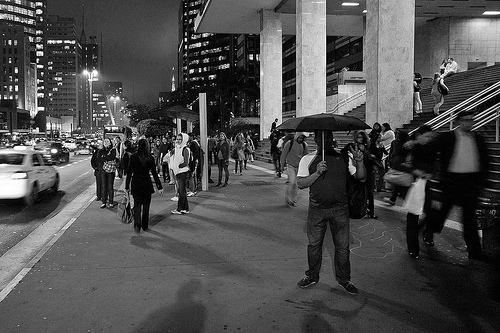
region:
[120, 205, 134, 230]
A gray bag in the photo.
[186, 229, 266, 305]
Road with tarmac in the photo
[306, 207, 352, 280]
Jeans in the photo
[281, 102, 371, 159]
Umbrella in the photo.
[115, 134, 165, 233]
A woman in the photo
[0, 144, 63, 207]
Car in the photo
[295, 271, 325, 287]
Black shoe in the photo.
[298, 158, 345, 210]
White and black t-shirt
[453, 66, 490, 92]
Stairs in the photo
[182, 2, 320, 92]
Buildings in the photo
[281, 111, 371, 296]
man standing on sidewalk holding umbrella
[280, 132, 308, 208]
man wearing hoodie walking down sidewalk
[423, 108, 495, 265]
man wearing a suit walking pass set of stairs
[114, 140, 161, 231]
woman wearing black coat walking on sidewalk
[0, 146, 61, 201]
white vehicle traveling down road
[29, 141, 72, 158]
dark colored vehicle traveling down road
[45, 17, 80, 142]
tall buildings with many windows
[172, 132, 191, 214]
boy wearing hood standing on sidewalk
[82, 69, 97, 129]
tall lamp post near buildings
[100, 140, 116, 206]
girl holding checkered bag standing on sidewalk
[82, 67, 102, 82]
street light beside tall building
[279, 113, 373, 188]
man in black and white shirt holding unbrella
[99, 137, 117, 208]
woman walking in sidewalk with checkered bag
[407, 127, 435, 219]
woman holding plastic grocery bag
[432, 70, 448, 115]
woman with large bag walking up stairs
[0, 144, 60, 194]
taxi cab passing by people on sidewalk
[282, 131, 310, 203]
man in grey hoodie with backpack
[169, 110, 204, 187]
many people waiting at bus stop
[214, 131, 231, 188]
man leather jacket looking at camera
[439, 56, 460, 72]
couple in white sitting atop the stairs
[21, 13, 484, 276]
this is a black and white photo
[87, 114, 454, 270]
there is a lot of activity in this shot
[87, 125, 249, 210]
people are out on the street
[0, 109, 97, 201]
lots of traffic is driving around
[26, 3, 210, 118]
it looks like a cloudy night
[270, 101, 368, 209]
this man has an umbrella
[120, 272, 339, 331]
these are peoples shadows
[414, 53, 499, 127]
these people are on the stairs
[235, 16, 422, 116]
pillars supporting a building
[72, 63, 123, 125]
lights shining above the street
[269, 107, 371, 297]
a man holding umbrella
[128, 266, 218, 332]
a dark shadow of a pedestrian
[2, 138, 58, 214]
a taxi riding down the street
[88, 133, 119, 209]
a woman with a checkered bag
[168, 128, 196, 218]
a woman wearing a hooded vest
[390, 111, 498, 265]
a couple walking by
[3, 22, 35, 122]
a small building with lights on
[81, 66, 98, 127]
a lit street light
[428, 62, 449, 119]
a person walking up stairs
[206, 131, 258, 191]
a crowd of people walking up street